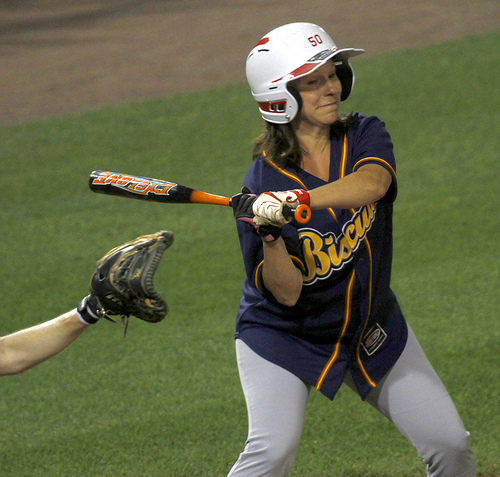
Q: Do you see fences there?
A: No, there are no fences.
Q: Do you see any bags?
A: No, there are no bags.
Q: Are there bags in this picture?
A: No, there are no bags.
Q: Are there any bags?
A: No, there are no bags.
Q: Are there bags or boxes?
A: No, there are no bags or boxes.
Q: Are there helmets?
A: Yes, there is a helmet.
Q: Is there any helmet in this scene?
A: Yes, there is a helmet.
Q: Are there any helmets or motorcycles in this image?
A: Yes, there is a helmet.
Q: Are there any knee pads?
A: No, there are no knee pads.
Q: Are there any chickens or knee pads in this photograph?
A: No, there are no knee pads or chickens.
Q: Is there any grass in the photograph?
A: Yes, there is grass.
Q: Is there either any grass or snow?
A: Yes, there is grass.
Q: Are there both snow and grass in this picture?
A: No, there is grass but no snow.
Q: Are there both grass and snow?
A: No, there is grass but no snow.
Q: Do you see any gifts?
A: No, there are no gifts.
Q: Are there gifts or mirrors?
A: No, there are no gifts or mirrors.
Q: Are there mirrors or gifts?
A: No, there are no gifts or mirrors.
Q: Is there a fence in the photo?
A: No, there are no fences.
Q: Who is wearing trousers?
A: The player is wearing trousers.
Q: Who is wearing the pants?
A: The player is wearing trousers.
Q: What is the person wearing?
A: The player is wearing pants.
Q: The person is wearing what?
A: The player is wearing pants.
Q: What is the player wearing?
A: The player is wearing pants.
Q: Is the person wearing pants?
A: Yes, the player is wearing pants.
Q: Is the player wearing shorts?
A: No, the player is wearing pants.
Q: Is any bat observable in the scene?
A: Yes, there is a bat.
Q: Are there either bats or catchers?
A: Yes, there is a bat.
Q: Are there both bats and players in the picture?
A: Yes, there are both a bat and a player.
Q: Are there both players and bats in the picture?
A: Yes, there are both a bat and a player.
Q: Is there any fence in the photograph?
A: No, there are no fences.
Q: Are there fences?
A: No, there are no fences.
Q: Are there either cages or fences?
A: No, there are no fences or cages.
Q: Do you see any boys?
A: No, there are no boys.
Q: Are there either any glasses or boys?
A: No, there are no boys or glasses.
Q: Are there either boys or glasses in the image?
A: No, there are no boys or glasses.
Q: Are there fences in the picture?
A: No, there are no fences.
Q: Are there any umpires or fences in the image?
A: No, there are no fences or umpires.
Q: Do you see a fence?
A: No, there are no fences.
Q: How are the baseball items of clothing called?
A: The clothing items are pants.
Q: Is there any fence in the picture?
A: No, there are no fences.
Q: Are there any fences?
A: No, there are no fences.